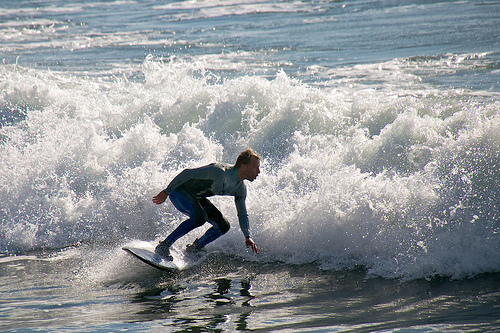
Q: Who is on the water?
A: The man.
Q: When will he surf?
A: Now.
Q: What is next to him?
A: Wave.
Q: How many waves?
A: 1.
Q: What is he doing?
A: Surfing.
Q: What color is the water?
A: White.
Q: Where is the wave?
A: Behind the man.